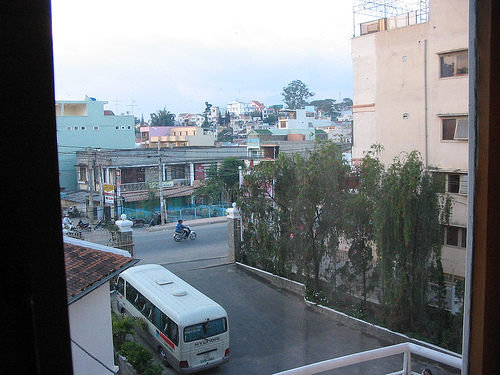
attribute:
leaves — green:
[403, 207, 415, 230]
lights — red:
[161, 356, 268, 373]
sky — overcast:
[50, 8, 360, 126]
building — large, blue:
[62, 95, 138, 225]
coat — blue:
[161, 226, 200, 242]